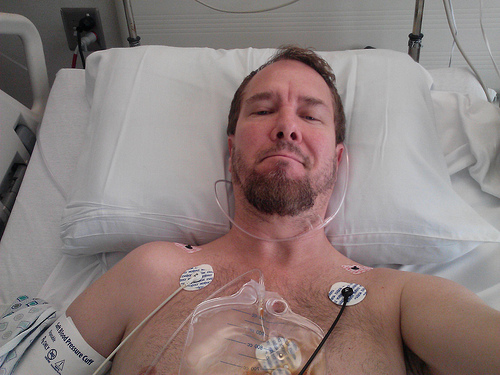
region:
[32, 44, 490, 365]
a man on a hospital bed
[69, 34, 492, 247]
his head is on a pillow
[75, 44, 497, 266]
the pillow is white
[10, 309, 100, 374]
a blood pressure check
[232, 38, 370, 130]
his hair is brown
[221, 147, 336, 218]
his beard is brown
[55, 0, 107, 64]
an outlet on the wall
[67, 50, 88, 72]
a red cord by the bed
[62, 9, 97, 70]
a black cord in the wall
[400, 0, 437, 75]
a silver bedpost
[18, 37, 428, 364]
a guy on the hospital bed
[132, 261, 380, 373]
chest of the guy with medical stuff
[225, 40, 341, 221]
facial expression of the guy on the bed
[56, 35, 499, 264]
a pillow the guy is using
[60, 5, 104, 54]
electrical socket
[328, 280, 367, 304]
a medical patch on the chest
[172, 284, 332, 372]
a medical bag on the chest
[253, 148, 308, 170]
mouth of the guy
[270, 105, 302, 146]
nose of the guy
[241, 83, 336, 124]
nose the eyebrow of the person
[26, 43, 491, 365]
Man laying in a hospital bed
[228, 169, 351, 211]
The man has a beard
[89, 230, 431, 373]
The man has no shirt on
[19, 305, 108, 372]
Blood pressure cuff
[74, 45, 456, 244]
Pillow under the man's head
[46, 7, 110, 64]
Outlet with two cords plugged in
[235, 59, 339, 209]
Man looking at the camera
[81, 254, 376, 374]
Devices connected to man's chest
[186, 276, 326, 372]
Plastic bag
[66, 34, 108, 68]
Red cord is under the black cord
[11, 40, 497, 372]
A man in a hospital bed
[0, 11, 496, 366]
A hospital bed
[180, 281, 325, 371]
A clear plastic bag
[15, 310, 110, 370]
A white blood pressure cuff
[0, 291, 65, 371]
A hospital gown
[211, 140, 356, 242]
a clear plastic tube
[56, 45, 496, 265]
A large white pillow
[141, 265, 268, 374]
a clear plastic tube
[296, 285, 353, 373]
A black wire attached to a man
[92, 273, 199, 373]
A white wire attached to a man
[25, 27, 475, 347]
man in a hospital bed with wires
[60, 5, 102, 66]
oxygen wires attached to the wall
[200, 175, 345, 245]
oxygen wire on mans face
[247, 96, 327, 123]
man's eyes on his face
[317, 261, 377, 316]
electrodes on man's chest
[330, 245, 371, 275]
electrode on man's shoulder